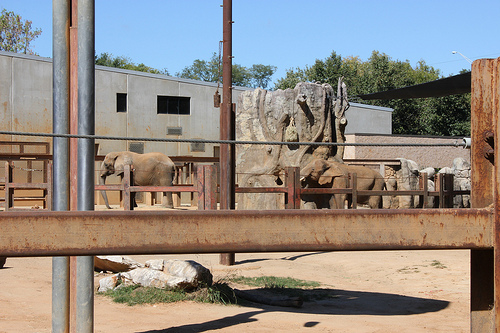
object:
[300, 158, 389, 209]
elephant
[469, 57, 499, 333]
pen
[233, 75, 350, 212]
rock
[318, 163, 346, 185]
ear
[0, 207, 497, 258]
pole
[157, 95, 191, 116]
window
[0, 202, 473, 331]
ground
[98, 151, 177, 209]
elephant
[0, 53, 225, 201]
wall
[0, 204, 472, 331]
dirt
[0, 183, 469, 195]
pen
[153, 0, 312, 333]
middle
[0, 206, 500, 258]
pen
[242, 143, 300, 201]
food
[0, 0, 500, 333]
zoo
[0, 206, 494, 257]
bar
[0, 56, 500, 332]
fence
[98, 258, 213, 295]
rock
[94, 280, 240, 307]
grass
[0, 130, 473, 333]
enclosure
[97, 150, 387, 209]
two elephants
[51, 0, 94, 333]
metal pole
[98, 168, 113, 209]
long trunk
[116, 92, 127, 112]
window on a building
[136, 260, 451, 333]
large shadow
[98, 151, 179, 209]
an elephant standing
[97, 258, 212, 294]
large stone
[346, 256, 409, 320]
patches of dirt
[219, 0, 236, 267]
brown metal pole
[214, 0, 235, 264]
iron fence pole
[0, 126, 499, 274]
secure enclosure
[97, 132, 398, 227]
looking for food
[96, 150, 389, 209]
enjoying the sun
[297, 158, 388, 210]
are all fully grown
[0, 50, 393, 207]
big building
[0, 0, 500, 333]
in daytime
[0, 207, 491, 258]
rusted metal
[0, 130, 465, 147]
rounded silver pipes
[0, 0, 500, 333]
an enclosure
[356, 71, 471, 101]
shade cover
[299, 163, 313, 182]
long trunk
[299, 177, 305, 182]
white tusk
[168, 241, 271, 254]
rust spot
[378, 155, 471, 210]
pile of rocks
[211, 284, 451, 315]
shadow in the dirt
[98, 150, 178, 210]
standing alone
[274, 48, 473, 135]
green trees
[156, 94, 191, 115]
black windows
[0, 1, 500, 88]
blue sky above